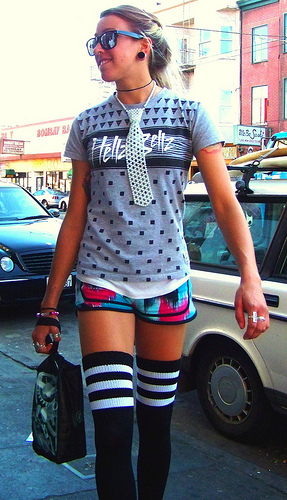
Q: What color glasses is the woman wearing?
A: Black.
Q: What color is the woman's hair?
A: Blonde.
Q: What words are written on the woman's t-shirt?
A: Hellz Bellz.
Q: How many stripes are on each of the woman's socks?
A: 3.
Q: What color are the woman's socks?
A: Black with white stripes.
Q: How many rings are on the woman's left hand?
A: 2.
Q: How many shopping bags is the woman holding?
A: 1.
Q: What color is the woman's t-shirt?
A: Grey.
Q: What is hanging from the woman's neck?
A: Necktie.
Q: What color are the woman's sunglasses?
A: Black and blue.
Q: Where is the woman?
A: On a city sidewalk.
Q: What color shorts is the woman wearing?
A: Blue, pink, and black.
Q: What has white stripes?
A: Stockings.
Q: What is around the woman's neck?
A: A tie.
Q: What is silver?
A: The hubcap.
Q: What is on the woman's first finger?
A: A ring.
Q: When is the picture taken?
A: Day time.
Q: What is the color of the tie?
A: Black and white.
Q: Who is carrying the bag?
A: A girl.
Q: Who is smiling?
A: The lady.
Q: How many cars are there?
A: 4.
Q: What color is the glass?
A: Black.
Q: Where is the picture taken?
A: Beside a city street.